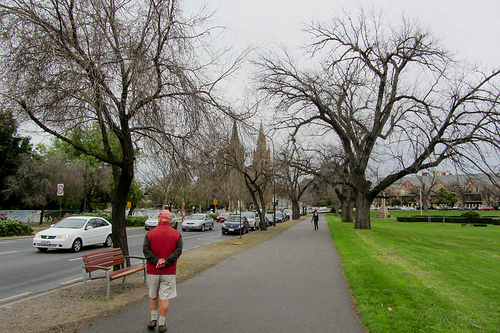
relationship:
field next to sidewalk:
[327, 208, 477, 331] [235, 199, 346, 328]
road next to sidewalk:
[11, 208, 213, 259] [235, 199, 346, 328]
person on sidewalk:
[140, 198, 179, 330] [251, 221, 353, 318]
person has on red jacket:
[140, 198, 179, 330] [142, 224, 183, 276]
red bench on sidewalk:
[81, 248, 146, 290] [86, 174, 368, 322]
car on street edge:
[222, 215, 248, 232] [183, 231, 265, 252]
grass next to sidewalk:
[181, 219, 284, 271] [202, 186, 351, 331]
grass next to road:
[181, 219, 284, 271] [15, 161, 218, 285]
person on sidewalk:
[140, 198, 179, 330] [50, 210, 372, 330]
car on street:
[32, 208, 117, 253] [2, 205, 257, 305]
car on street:
[144, 179, 234, 261] [75, 202, 253, 313]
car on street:
[182, 210, 216, 232] [1, 218, 274, 308]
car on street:
[32, 208, 117, 253] [1, 214, 239, 306]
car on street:
[222, 215, 248, 232] [0, 238, 93, 297]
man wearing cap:
[127, 201, 187, 331] [158, 208, 174, 220]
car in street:
[32, 208, 117, 253] [3, 207, 227, 294]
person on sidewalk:
[306, 204, 323, 231] [300, 200, 332, 247]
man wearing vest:
[98, 201, 255, 331] [142, 232, 182, 272]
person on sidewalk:
[306, 204, 323, 231] [239, 239, 348, 325]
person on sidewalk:
[306, 204, 323, 231] [248, 232, 330, 319]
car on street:
[213, 195, 315, 240] [10, 235, 59, 288]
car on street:
[151, 212, 237, 239] [165, 167, 360, 332]